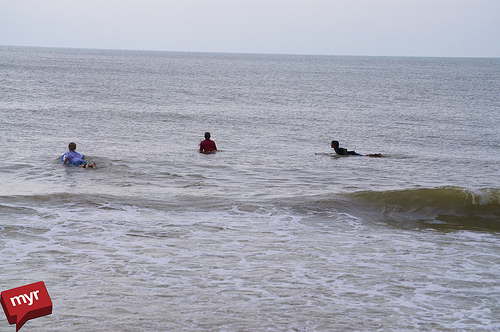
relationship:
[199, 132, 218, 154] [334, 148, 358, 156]
boy in clothing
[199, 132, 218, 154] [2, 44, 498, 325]
boy in water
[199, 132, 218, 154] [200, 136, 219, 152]
boy in clothing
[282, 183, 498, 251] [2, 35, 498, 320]
wave in ocean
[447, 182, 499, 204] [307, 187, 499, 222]
crest of wave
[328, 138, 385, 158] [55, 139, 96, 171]
boy in boy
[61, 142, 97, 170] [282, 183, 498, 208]
boy in wave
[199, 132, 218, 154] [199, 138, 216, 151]
boy in red shirt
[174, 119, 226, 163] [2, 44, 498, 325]
boy on water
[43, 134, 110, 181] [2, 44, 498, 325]
boy water on water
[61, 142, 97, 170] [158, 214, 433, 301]
boy in water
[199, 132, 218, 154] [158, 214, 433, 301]
boy in water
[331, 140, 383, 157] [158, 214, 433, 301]
boy in water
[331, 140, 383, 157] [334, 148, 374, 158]
boy wearing clothing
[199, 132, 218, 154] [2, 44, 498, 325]
boy sitting up in water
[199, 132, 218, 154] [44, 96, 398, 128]
boy paddling to waves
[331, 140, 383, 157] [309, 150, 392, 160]
boy laying on surfboard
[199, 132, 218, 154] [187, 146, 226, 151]
boy laying on surfboard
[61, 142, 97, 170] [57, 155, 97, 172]
boy laying on surfboard